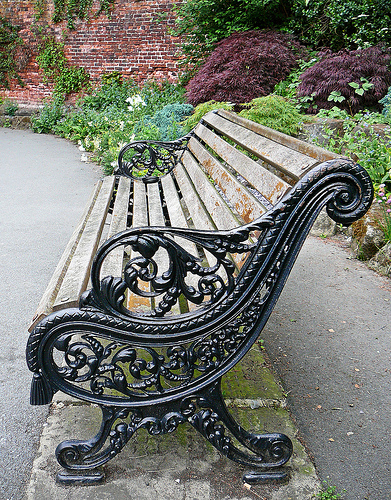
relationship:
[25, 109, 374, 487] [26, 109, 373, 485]
bench has edges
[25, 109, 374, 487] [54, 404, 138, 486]
bench has a leg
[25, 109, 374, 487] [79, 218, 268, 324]
bench has an arm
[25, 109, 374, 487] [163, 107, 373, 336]
bench has a backrest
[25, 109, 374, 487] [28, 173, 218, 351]
bench has a seat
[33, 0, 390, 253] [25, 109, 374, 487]
bushes near bench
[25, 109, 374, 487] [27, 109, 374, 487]
bench has metal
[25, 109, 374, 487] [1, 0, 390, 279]
bench in garden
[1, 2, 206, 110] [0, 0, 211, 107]
wall covered in ivy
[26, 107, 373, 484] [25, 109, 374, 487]
design on bench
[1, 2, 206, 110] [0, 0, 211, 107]
wall covered with ivy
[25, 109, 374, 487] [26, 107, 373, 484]
bench has a design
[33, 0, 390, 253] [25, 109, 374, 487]
bushes behind bench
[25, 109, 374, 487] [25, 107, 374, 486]
bench has curves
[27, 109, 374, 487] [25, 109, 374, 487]
metal on sides of bench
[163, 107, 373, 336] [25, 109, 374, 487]
backrest of bench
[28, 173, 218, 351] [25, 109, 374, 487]
seat of bench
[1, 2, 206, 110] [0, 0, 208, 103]
wall made of brick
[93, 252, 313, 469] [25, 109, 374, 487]
moss under bench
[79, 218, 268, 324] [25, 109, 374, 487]
arm on bench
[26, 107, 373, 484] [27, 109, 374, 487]
design on metal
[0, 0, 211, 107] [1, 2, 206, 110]
ivy on wall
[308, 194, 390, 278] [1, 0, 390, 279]
rocks in garden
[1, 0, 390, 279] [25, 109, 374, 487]
garden has a bench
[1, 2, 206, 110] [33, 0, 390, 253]
wall near bushes